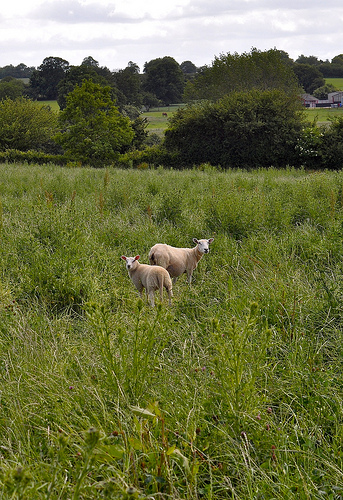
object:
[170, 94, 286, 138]
person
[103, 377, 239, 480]
green grass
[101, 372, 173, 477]
tall grass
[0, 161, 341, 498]
field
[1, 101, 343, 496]
grass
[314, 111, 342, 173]
tree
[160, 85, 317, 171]
tree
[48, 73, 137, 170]
tree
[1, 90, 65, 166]
tree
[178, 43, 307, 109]
tree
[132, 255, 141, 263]
ear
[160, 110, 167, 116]
horse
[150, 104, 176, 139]
field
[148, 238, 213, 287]
sheep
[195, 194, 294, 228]
bushes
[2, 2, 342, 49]
clouds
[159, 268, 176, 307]
tail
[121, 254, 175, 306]
sheep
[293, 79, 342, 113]
buildings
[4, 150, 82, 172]
green bushes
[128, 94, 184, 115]
fence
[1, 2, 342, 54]
cloud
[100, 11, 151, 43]
white clouds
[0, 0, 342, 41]
blue sky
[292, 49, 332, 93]
trees